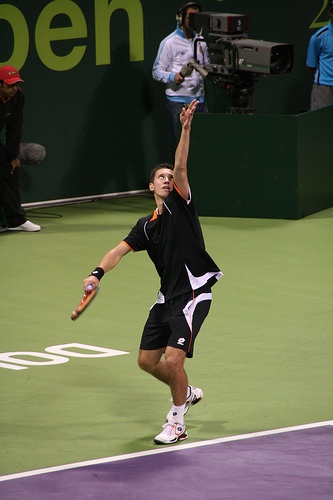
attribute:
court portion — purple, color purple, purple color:
[0, 419, 332, 500]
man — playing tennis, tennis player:
[70, 98, 223, 444]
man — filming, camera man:
[150, 1, 211, 152]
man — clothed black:
[0, 63, 42, 232]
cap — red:
[0, 63, 25, 86]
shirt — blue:
[305, 19, 332, 88]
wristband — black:
[89, 266, 104, 280]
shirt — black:
[122, 175, 222, 303]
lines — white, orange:
[143, 181, 192, 243]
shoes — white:
[153, 382, 205, 448]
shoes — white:
[3, 219, 39, 235]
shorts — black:
[137, 284, 212, 357]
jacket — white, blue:
[150, 25, 210, 106]